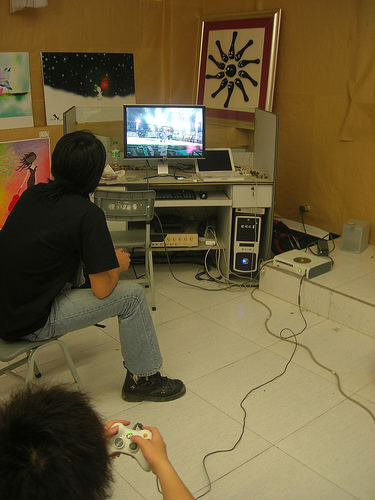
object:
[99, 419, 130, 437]
hand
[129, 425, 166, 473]
hand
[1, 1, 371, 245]
wall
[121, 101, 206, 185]
computer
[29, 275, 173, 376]
jean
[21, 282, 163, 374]
blue jeans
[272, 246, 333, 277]
xbox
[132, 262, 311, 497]
cord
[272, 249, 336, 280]
console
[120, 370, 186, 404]
shoe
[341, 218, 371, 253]
speaker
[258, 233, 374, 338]
step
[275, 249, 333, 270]
disk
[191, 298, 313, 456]
floor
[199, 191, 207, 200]
mouse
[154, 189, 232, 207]
drawer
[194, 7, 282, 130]
artwork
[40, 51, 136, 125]
artwork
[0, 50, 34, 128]
artwork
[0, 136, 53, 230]
artwork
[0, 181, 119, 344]
shirt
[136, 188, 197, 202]
keyboard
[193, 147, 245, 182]
laptop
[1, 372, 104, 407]
hair brush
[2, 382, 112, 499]
head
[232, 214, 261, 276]
modem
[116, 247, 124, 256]
thumb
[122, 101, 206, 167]
flat screen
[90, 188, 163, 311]
chair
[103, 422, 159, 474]
controller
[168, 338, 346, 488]
ground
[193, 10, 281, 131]
framed art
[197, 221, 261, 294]
cords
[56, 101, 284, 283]
desk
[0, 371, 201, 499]
guy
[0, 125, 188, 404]
guy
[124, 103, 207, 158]
video game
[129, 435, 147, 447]
thumb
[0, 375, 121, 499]
hair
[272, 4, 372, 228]
paper